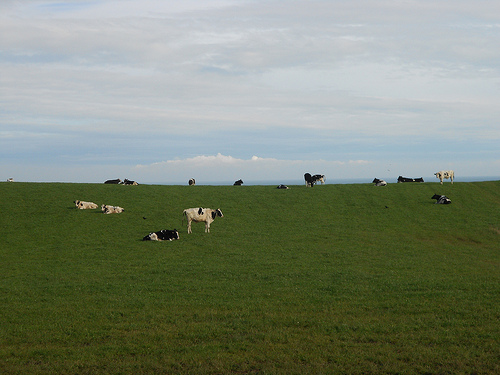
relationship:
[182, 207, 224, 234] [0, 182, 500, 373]
cow on grass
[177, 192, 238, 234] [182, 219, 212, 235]
cow has legs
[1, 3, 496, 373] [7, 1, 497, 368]
picture of outdoor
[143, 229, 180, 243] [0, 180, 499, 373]
cow in field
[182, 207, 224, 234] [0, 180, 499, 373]
cow in field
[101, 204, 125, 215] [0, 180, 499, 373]
cow in field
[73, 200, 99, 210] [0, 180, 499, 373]
cow in field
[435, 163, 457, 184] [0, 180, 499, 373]
cow in field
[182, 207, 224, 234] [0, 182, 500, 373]
cow eats grass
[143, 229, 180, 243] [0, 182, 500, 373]
cow eats grass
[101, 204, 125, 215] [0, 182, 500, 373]
cow eats grass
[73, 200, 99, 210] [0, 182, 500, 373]
cow eats grass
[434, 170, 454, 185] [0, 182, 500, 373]
cow eats grass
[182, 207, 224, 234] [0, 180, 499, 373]
cow lying field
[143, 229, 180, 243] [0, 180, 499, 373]
cow lying field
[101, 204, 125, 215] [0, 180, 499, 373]
cow lying field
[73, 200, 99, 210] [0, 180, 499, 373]
cow lying field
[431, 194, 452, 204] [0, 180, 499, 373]
cow lying field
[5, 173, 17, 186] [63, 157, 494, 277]
farmer has cows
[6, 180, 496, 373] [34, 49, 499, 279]
farm has cows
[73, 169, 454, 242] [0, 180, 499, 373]
cows in field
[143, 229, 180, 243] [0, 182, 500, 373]
cow in grass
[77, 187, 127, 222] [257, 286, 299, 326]
cows in grass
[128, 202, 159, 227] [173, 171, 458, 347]
bird in field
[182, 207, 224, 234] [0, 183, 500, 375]
cow in farm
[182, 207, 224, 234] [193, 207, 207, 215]
cow with spots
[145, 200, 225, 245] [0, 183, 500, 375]
cows on farm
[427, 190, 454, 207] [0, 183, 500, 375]
cow on farm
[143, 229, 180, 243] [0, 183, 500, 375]
cow on farm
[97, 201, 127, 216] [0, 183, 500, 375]
cow on farm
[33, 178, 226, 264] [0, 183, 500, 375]
four cows on farm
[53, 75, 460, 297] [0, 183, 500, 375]
cows on farm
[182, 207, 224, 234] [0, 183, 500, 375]
cow on farm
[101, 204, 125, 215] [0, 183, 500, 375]
cow on farm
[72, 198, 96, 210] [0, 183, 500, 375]
cow on farm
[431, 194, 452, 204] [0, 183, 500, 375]
cow on farm